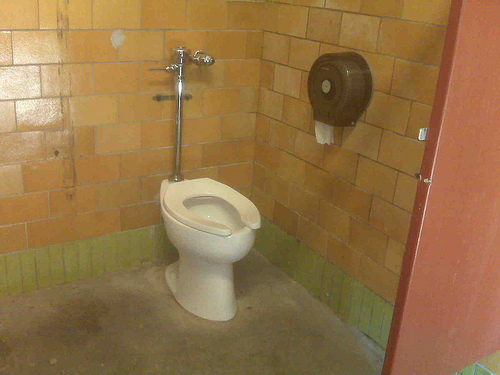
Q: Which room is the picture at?
A: It is at the bathroom.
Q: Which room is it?
A: It is a bathroom.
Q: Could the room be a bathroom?
A: Yes, it is a bathroom.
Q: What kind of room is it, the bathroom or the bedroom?
A: It is the bathroom.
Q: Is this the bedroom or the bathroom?
A: It is the bathroom.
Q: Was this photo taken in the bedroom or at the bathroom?
A: It was taken at the bathroom.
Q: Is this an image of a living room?
A: No, the picture is showing a bathroom.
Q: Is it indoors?
A: Yes, it is indoors.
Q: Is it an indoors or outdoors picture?
A: It is indoors.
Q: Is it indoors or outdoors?
A: It is indoors.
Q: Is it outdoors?
A: No, it is indoors.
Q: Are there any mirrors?
A: No, there are no mirrors.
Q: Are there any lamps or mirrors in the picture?
A: No, there are no mirrors or lamps.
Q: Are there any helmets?
A: No, there are no helmets.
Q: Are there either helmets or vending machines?
A: No, there are no helmets or vending machines.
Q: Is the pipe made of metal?
A: Yes, the pipe is made of metal.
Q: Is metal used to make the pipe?
A: Yes, the pipe is made of metal.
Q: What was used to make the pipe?
A: The pipe is made of metal.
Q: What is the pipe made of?
A: The pipe is made of metal.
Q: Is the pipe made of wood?
A: No, the pipe is made of metal.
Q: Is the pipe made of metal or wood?
A: The pipe is made of metal.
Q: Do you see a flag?
A: No, there are no flags.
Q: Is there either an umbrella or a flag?
A: No, there are no flags or umbrellas.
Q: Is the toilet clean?
A: Yes, the toilet is clean.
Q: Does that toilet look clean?
A: Yes, the toilet is clean.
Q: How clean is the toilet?
A: The toilet is clean.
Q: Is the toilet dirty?
A: No, the toilet is clean.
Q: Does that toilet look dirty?
A: No, the toilet is clean.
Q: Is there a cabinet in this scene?
A: No, there are no cabinets.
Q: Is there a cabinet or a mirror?
A: No, there are no cabinets or mirrors.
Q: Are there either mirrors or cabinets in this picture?
A: No, there are no cabinets or mirrors.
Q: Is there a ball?
A: No, there are no balls.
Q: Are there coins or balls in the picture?
A: No, there are no balls or coins.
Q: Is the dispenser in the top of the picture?
A: Yes, the dispenser is in the top of the image.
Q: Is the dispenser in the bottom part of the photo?
A: No, the dispenser is in the top of the image.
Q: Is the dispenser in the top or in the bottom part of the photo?
A: The dispenser is in the top of the image.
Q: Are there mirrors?
A: No, there are no mirrors.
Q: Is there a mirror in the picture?
A: No, there are no mirrors.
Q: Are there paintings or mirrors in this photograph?
A: No, there are no mirrors or paintings.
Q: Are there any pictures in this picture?
A: No, there are no pictures.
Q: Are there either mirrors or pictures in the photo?
A: No, there are no pictures or mirrors.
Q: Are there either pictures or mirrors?
A: No, there are no pictures or mirrors.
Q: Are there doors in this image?
A: Yes, there is a door.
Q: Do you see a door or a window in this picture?
A: Yes, there is a door.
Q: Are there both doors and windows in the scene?
A: No, there is a door but no windows.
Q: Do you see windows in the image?
A: No, there are no windows.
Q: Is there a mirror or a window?
A: No, there are no windows or mirrors.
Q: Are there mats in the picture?
A: No, there are no mats.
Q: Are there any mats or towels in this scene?
A: No, there are no mats or towels.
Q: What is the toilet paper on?
A: The toilet paper is on the wall.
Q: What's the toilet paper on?
A: The toilet paper is on the wall.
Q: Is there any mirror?
A: No, there are no mirrors.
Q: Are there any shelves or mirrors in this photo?
A: No, there are no mirrors or shelves.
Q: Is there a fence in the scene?
A: No, there are no fences.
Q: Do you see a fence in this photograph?
A: No, there are no fences.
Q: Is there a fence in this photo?
A: No, there are no fences.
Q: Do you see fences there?
A: No, there are no fences.